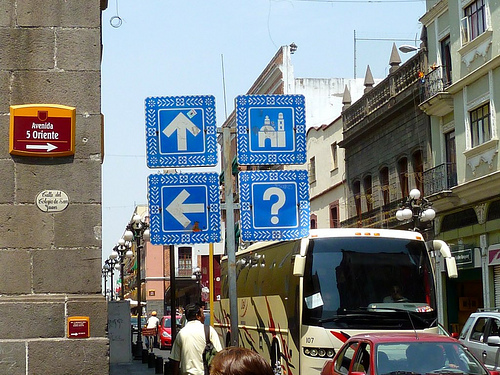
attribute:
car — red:
[318, 330, 498, 372]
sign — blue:
[144, 168, 227, 248]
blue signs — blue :
[159, 74, 360, 264]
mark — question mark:
[254, 174, 309, 251]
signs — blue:
[120, 76, 328, 258]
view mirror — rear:
[441, 240, 459, 281]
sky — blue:
[102, 0, 427, 297]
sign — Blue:
[127, 81, 229, 179]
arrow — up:
[161, 113, 201, 157]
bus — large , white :
[210, 220, 445, 374]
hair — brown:
[226, 354, 248, 369]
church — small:
[253, 105, 291, 152]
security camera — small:
[394, 42, 423, 54]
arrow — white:
[161, 112, 202, 153]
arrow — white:
[163, 188, 204, 227]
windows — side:
[222, 247, 298, 294]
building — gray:
[153, 40, 499, 356]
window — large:
[298, 231, 439, 331]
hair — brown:
[204, 344, 270, 372]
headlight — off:
[304, 346, 336, 360]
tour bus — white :
[212, 227, 448, 368]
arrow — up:
[148, 99, 211, 161]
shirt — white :
[160, 323, 223, 373]